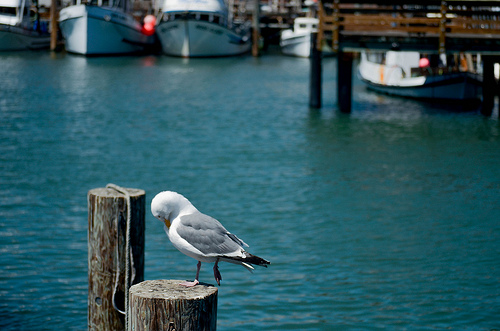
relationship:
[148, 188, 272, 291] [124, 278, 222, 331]
bird on pole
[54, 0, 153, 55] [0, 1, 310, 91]
blue boat in harbor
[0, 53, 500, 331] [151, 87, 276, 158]
water in river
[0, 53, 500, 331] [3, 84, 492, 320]
water in river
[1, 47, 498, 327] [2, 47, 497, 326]
water in river